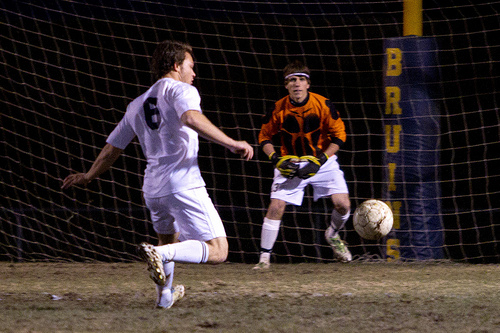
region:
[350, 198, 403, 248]
white soccer ball mid air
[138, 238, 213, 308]
man wearing knee length soccer socks and white shoes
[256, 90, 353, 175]
goalie wearing orange shirt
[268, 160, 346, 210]
goalie wearing white shorts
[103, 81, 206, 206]
soccer player wearing numbered white jersey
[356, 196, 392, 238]
a soccer ball in the air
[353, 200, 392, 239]
a dirty white and brown soccer ball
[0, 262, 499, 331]
brown ground covered in leaves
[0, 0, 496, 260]
large soccer net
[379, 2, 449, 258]
yellow and blue post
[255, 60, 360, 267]
goal keeper in orange shirt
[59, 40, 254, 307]
soccer player wearing a white uniform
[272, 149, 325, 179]
black and yellow gloves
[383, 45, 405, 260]
BRUINS in yellow writing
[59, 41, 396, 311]
a soccer player kicking ball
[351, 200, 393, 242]
a dirty white soccer ball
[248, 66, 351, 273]
a soccer goalie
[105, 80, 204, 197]
a white soccer jersey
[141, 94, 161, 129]
player number 6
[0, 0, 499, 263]
a white soccer net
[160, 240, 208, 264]
a white sock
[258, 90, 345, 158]
a black and orange jersey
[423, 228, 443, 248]
a square hole in a net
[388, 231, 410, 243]
a square hole in a net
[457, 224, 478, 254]
a square hole in a net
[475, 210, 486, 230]
a square hole in a net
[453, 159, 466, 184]
a square hole in a net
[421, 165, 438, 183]
a square hole in a net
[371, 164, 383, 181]
a square hole in a net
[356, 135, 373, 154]
a square hole in a net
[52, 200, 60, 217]
a square hole in a net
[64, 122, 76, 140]
a square hole in a net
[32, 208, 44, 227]
a hole in a net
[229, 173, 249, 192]
a hole in a net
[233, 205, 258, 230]
a hole in a net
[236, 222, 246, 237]
a hole in a net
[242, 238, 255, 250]
a hole in a net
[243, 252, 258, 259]
a hole in a net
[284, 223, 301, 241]
a hole in a net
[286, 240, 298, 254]
a hole in a net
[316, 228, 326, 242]
a hole in a net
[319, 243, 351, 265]
a hole in a net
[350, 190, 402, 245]
This is a ball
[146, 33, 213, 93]
This is a head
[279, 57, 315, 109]
This is a head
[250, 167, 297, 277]
Leg of a man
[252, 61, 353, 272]
player wearing orange shirt and white plates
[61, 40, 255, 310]
player wearing white pants and a white shirt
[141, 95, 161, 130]
number 6 on the player's shirt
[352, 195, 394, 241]
soccer ball the men are kicking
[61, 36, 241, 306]
A person is playing.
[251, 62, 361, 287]
A person is playing.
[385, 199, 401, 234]
A letter on a sign.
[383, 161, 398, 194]
A letter on a sign.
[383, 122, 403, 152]
A letter on a sign.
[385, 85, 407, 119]
A letter on a sign.